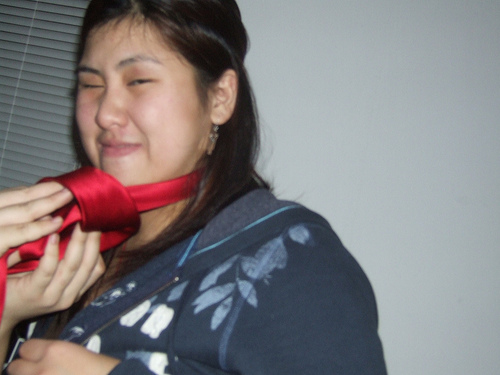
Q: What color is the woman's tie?
A: Red.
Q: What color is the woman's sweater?
A: Blue.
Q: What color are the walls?
A: White.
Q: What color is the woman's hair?
A: Brown.